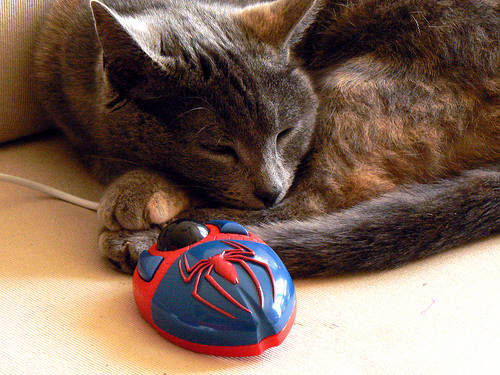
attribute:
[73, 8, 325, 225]
cat — sleeping, brown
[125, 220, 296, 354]
mouse — blue, black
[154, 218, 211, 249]
ball — black, shiny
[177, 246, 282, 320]
spider — red